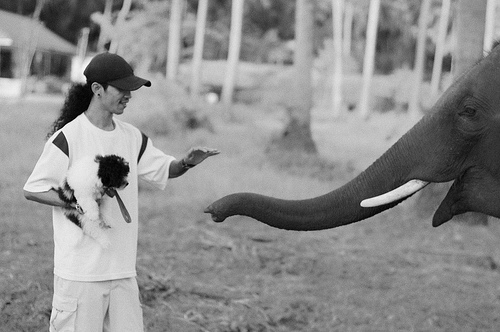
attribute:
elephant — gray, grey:
[204, 40, 499, 231]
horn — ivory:
[360, 178, 431, 207]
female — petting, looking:
[23, 53, 222, 331]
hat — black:
[85, 53, 152, 91]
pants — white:
[51, 276, 144, 331]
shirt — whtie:
[24, 109, 177, 282]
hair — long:
[48, 82, 94, 136]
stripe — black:
[54, 132, 69, 157]